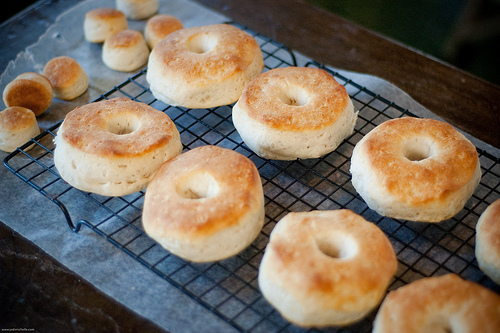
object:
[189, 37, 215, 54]
hole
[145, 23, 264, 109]
biscuit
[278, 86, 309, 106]
hole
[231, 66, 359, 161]
biscuit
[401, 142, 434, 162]
hole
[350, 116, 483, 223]
biscuit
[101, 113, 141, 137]
hole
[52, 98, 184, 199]
biscuit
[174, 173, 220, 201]
hole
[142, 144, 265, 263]
biscuit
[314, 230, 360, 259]
hole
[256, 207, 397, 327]
biscuit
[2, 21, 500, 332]
rack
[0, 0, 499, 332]
paper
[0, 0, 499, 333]
area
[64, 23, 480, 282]
wrinkle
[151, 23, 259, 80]
top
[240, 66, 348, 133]
top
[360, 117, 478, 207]
top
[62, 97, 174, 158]
top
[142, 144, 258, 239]
top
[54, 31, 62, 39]
hole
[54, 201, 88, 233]
leg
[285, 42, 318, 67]
leg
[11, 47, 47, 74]
tear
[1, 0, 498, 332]
table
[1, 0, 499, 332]
picture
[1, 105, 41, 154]
ball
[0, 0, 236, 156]
side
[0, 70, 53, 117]
ball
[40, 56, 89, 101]
ball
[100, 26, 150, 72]
ball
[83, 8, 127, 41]
ball